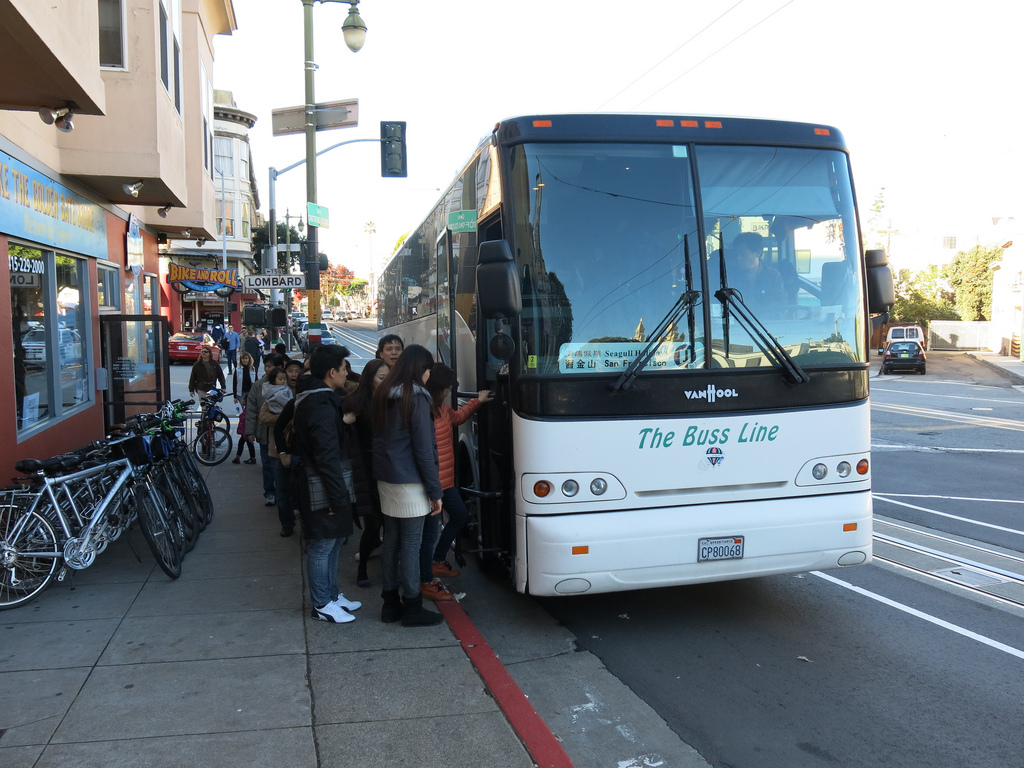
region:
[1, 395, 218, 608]
row of parked bicycles outside a store front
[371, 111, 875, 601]
commuter bus picking up passengers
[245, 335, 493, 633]
passengers waiting to board a bus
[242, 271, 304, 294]
street sign for Lomabrd St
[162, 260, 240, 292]
blue and orange sign advertising Bike and Roll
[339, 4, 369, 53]
street lamp with frosted globe over bulb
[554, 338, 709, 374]
sign for San Francisco in bus window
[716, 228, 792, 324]
bus driver visible through windshield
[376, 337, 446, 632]
Person standing is wearing dark jacket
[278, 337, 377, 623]
Person standing is wearing dark jacket and white sneakers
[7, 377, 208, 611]
Row of bicycles next to building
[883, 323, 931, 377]
Two vehicles parked in driveway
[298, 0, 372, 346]
Tall street light on the sidewalk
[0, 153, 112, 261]
Blue sign on building above window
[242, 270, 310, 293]
White street sign with black letters above sidewalk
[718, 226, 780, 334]
Person sitting in drivers seat on bus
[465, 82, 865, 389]
a view of glass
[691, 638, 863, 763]
a view of road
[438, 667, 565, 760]
a view of line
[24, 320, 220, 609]
a view of cycles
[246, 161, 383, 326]
a view of pole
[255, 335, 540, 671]
a group of passengers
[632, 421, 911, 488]
name on the bus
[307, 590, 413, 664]
shoe of the person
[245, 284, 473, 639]
several people lined up to get on the bus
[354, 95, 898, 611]
a large white and black bus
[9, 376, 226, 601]
a row of parked bikes outside the store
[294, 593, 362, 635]
white and black shoes on his feet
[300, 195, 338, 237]
a green and white sign on the pole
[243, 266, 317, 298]
a white and black sign on the pole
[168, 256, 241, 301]
a Bike and Roll sign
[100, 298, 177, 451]
open glass doors to a business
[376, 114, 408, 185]
the back side of a traffic light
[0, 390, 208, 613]
bikes parked at rack next to bus stop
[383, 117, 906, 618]
black and white city bus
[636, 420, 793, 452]
word the buss line written in blue on bus front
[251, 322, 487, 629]
crowd of people lined up to board bus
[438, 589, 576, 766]
red curbed no parking zone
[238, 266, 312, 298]
white street name sign for Lombard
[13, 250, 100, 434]
front window of store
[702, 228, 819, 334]
bus driver seated at the wheel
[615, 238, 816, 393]
wipers for large front of bus windows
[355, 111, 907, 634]
large white city bus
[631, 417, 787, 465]
green letters on front of bus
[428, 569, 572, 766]
red painted curb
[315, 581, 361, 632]
white and black sneakers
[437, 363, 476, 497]
orange puffy jacket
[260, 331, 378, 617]
man wearing sneakers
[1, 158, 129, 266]
blue store sign on wall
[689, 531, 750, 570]
white license plate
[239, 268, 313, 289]
white and black sign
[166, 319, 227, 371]
red sedan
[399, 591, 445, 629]
a girl's black boot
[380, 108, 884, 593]
a large black and white bus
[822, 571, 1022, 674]
a long white line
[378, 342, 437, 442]
a girl's long dark hair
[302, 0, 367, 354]
a tall street light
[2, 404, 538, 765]
a paved sidewalk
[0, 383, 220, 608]
a row of bikes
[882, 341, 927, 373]
the back of a car